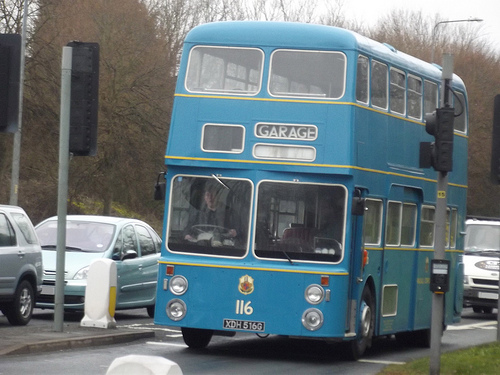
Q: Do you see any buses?
A: Yes, there is a bus.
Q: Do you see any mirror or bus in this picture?
A: Yes, there is a bus.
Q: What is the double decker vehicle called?
A: The vehicle is a bus.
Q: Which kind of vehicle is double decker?
A: The vehicle is a bus.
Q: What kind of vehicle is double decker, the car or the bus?
A: The bus is double decker.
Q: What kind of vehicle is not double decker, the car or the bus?
A: The car is not double decker.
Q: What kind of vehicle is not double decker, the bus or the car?
A: The car is not double decker.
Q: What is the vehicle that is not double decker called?
A: The vehicle is a car.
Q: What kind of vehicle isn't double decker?
A: The vehicle is a car.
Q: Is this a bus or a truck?
A: This is a bus.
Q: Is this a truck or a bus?
A: This is a bus.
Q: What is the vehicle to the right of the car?
A: The vehicle is a bus.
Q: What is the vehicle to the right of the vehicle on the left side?
A: The vehicle is a bus.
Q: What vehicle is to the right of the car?
A: The vehicle is a bus.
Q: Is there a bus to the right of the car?
A: Yes, there is a bus to the right of the car.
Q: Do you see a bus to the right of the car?
A: Yes, there is a bus to the right of the car.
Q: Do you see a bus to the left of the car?
A: No, the bus is to the right of the car.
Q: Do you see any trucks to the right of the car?
A: No, there is a bus to the right of the car.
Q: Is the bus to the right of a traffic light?
A: No, the bus is to the right of the car.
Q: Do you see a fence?
A: No, there are no fences.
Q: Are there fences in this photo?
A: No, there are no fences.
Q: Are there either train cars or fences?
A: No, there are no fences or train cars.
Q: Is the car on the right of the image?
A: No, the car is on the left of the image.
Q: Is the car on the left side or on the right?
A: The car is on the left of the image.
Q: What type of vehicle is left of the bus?
A: The vehicle is a car.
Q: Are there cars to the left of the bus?
A: Yes, there is a car to the left of the bus.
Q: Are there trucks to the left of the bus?
A: No, there is a car to the left of the bus.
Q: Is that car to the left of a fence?
A: No, the car is to the left of the bus.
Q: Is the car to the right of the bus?
A: No, the car is to the left of the bus.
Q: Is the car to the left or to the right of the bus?
A: The car is to the left of the bus.